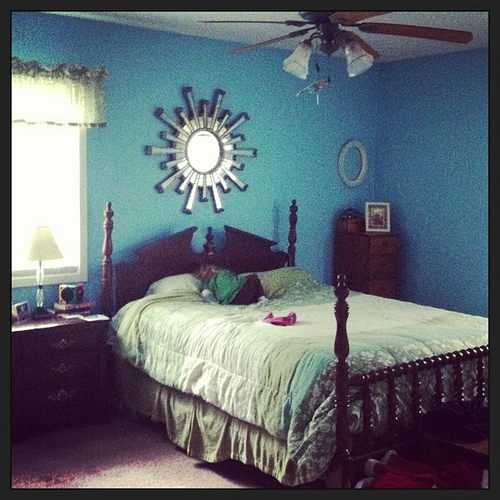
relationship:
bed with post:
[98, 201, 496, 436] [100, 200, 118, 313]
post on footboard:
[386, 377, 400, 442] [329, 271, 499, 492]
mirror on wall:
[137, 78, 271, 221] [11, 9, 383, 405]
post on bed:
[288, 199, 297, 267] [98, 194, 487, 489]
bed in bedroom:
[98, 201, 489, 489] [11, 12, 488, 488]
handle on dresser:
[47, 333, 83, 354] [13, 310, 114, 446]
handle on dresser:
[47, 389, 77, 404] [13, 310, 114, 446]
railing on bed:
[358, 354, 490, 443] [98, 201, 496, 436]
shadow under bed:
[193, 458, 329, 488] [98, 194, 487, 489]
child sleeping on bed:
[194, 264, 269, 307] [98, 194, 487, 489]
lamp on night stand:
[26, 227, 63, 320] [0, 299, 125, 438]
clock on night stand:
[58, 282, 81, 305] [11, 308, 108, 443]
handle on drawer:
[51, 364, 72, 372] [11, 348, 108, 384]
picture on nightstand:
[12, 301, 32, 325] [10, 309, 110, 441]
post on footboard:
[330, 273, 353, 465] [293, 339, 483, 413]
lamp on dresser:
[26, 227, 63, 320] [13, 310, 114, 446]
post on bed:
[99, 201, 118, 426] [98, 194, 487, 489]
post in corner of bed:
[281, 194, 303, 256] [98, 194, 487, 489]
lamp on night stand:
[19, 224, 66, 319] [0, 299, 125, 438]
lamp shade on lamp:
[22, 220, 77, 263] [20, 211, 72, 326]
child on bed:
[194, 262, 272, 305] [98, 194, 487, 489]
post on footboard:
[330, 273, 353, 465] [334, 271, 489, 463]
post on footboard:
[362, 383, 375, 451] [334, 271, 489, 463]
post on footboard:
[386, 377, 400, 442] [334, 271, 489, 463]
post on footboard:
[435, 365, 446, 410] [334, 271, 489, 463]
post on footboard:
[412, 369, 420, 431] [334, 271, 489, 463]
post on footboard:
[329, 270, 369, 472] [328, 274, 483, 459]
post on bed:
[99, 201, 115, 316] [98, 194, 487, 489]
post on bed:
[330, 273, 353, 465] [98, 194, 487, 489]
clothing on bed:
[254, 305, 304, 332] [98, 194, 487, 489]